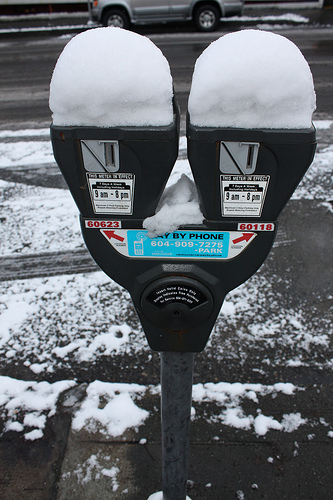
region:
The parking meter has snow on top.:
[30, 38, 326, 140]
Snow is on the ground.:
[12, 368, 266, 443]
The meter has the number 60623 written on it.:
[70, 212, 137, 239]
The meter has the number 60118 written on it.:
[230, 216, 308, 244]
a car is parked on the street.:
[73, 4, 227, 40]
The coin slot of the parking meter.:
[81, 131, 138, 177]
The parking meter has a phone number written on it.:
[140, 221, 229, 271]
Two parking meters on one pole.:
[43, 94, 315, 343]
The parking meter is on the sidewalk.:
[47, 91, 279, 391]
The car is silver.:
[81, 1, 264, 36]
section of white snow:
[229, 391, 244, 395]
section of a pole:
[173, 402, 177, 450]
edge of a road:
[103, 424, 143, 461]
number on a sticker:
[237, 224, 268, 230]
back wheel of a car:
[200, 8, 216, 21]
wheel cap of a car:
[197, 8, 212, 32]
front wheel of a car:
[111, 6, 120, 20]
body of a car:
[150, 4, 181, 18]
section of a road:
[171, 44, 183, 47]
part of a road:
[16, 40, 37, 76]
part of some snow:
[236, 76, 272, 100]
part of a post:
[158, 431, 181, 458]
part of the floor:
[236, 456, 274, 481]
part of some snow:
[227, 404, 258, 433]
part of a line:
[200, 429, 231, 452]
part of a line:
[232, 439, 250, 449]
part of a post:
[163, 435, 189, 473]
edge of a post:
[166, 406, 185, 444]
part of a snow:
[99, 409, 127, 439]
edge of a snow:
[102, 430, 129, 448]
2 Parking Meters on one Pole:
[41, 4, 322, 234]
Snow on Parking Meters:
[41, 24, 320, 354]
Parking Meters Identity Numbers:
[76, 212, 281, 240]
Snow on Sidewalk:
[2, 364, 327, 492]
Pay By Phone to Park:
[127, 220, 228, 261]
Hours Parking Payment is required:
[213, 168, 270, 220]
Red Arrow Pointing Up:
[225, 229, 255, 243]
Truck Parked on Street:
[79, 0, 247, 27]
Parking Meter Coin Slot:
[211, 137, 266, 175]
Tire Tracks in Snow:
[4, 104, 52, 294]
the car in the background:
[82, 1, 260, 40]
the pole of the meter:
[132, 349, 229, 497]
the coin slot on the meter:
[73, 130, 129, 179]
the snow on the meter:
[39, 17, 175, 133]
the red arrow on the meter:
[100, 227, 127, 245]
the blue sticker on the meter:
[126, 226, 231, 259]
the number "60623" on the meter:
[81, 216, 127, 229]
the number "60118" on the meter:
[231, 214, 280, 242]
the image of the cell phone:
[133, 235, 147, 257]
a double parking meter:
[42, 21, 325, 496]